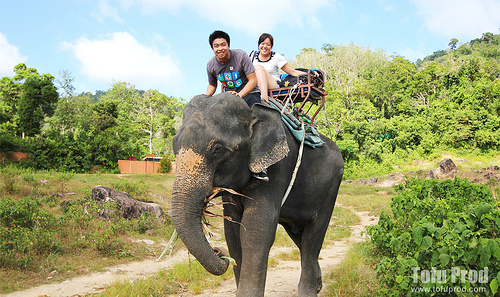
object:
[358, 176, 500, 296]
bush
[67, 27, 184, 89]
cloud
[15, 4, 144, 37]
sky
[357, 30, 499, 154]
trees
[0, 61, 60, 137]
tree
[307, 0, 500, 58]
sky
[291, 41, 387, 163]
trees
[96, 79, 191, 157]
trees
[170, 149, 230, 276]
grass trunk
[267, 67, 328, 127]
red seating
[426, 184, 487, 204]
foliage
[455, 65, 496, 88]
foliage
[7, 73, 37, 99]
foliage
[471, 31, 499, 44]
forest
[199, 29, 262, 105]
man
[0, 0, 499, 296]
picture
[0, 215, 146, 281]
grass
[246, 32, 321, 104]
person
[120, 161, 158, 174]
wall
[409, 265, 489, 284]
name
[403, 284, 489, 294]
lettering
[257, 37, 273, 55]
face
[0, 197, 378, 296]
path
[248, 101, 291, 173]
ear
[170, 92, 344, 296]
elephant